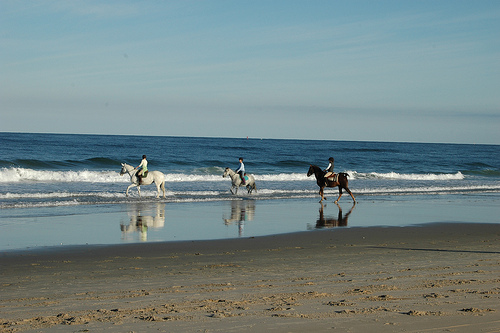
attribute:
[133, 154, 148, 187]
person — happy, riding, holding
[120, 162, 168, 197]
horse — white, running, ridden, beautiful, walking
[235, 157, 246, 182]
person — man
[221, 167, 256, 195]
horse — white, running, middle, grey, ridden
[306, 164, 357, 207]
horse — brown, dark, running, black, ridden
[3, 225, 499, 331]
sand — wet, piled, used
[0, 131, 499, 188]
ocean — blue, expanse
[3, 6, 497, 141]
sky — hazy, blue, light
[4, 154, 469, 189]
waves — white, coming, small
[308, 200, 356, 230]
reflection — shadow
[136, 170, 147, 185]
saddle — brown